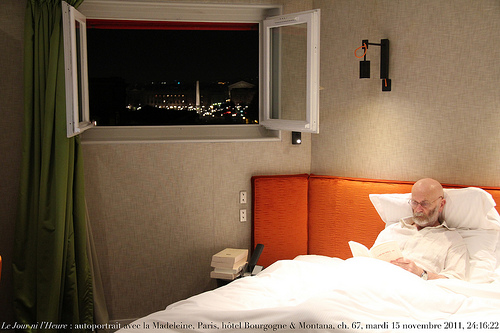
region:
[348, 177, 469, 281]
an old man reading in the bed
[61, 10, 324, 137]
the window is open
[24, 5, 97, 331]
the green curtain isnt drawn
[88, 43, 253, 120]
the city can be seen from the room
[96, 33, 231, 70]
it is dark ouside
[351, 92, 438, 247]
the lights are switched on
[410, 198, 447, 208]
the man is wearing spectacles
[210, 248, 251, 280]
books are stacked on the bed side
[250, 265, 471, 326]
the bed coverings are white in colour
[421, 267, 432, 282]
the man is wearing a watch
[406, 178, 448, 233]
a person wearing specks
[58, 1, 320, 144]
a window with glass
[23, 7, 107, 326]
green colour curtains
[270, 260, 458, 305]
white colour blanket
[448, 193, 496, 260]
white colour pillow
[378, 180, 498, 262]
a man is using white colour pillow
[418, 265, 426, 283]
a man wearing black colour wrist watch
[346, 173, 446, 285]
a person reading some books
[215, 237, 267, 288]
some books kept in the table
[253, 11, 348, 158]
a white colour window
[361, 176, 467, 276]
A man in the bed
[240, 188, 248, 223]
Outlets on the wall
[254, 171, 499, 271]
The back of the bed is orange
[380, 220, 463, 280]
The man is wearing a white shirt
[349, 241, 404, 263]
The man is reading a white boook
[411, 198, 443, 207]
The man is wearing glasses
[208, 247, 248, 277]
Books on the beside table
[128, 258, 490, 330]
The bed sheets are white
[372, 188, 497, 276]
A pillow behind the man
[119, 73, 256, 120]
City lights outside the window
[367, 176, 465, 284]
Older man sitting in bed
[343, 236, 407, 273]
Book being read by man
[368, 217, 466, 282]
White shirt worn by man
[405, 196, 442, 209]
Glasses worn by man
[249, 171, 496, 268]
Orange headboard behind the man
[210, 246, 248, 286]
Stack of books on night stand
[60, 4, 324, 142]
Window in open position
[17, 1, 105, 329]
Green current for the window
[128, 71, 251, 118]
City lights through the window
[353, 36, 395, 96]
Light on wall over the bed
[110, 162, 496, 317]
man in bed reading book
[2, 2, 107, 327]
green draperies on side of open window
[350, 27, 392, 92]
thin black lighting fixture attached to wall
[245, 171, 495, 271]
cushioned orange headboard panels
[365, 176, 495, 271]
pillows propped up behind back and head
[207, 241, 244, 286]
pile of books by side of bed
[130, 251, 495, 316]
white comforter over bed and man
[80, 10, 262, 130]
dark night with lights across town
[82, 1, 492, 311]
tan wallpaper of muted rectangles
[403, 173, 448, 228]
bald head with beard and eyeglasses